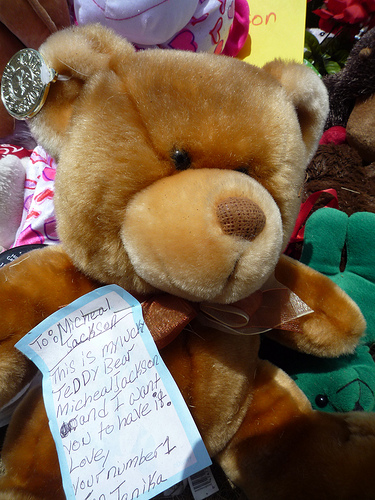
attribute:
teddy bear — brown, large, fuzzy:
[4, 26, 375, 499]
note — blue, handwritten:
[15, 284, 214, 500]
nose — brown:
[216, 196, 269, 239]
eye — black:
[169, 148, 192, 169]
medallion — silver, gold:
[4, 47, 50, 118]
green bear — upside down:
[284, 211, 374, 407]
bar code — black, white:
[188, 473, 221, 496]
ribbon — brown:
[131, 292, 308, 336]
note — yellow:
[240, 1, 306, 68]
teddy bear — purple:
[1, 1, 246, 245]